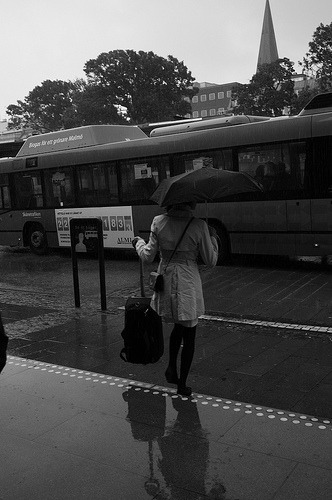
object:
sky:
[0, 1, 331, 120]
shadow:
[121, 386, 225, 498]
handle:
[139, 258, 146, 296]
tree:
[5, 47, 199, 129]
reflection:
[123, 383, 225, 499]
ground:
[1, 246, 331, 498]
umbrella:
[147, 166, 263, 208]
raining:
[1, 397, 331, 500]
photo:
[1, 1, 330, 499]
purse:
[146, 271, 165, 294]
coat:
[134, 206, 220, 322]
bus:
[0, 93, 332, 257]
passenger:
[275, 158, 285, 178]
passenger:
[255, 163, 265, 182]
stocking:
[179, 325, 196, 385]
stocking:
[166, 323, 181, 367]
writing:
[115, 234, 133, 246]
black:
[259, 443, 330, 500]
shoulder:
[187, 214, 207, 230]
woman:
[132, 201, 219, 396]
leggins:
[168, 320, 196, 384]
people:
[262, 160, 273, 191]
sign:
[69, 217, 107, 311]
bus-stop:
[1, 91, 330, 309]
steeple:
[255, 0, 279, 71]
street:
[0, 287, 332, 417]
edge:
[143, 467, 228, 499]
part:
[1, 370, 122, 499]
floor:
[1, 243, 330, 499]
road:
[0, 254, 332, 325]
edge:
[217, 262, 331, 326]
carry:
[120, 234, 165, 365]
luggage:
[118, 296, 165, 364]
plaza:
[0, 356, 330, 500]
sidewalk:
[0, 355, 332, 500]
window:
[12, 173, 43, 210]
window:
[45, 170, 73, 207]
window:
[123, 164, 170, 207]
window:
[238, 149, 310, 194]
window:
[77, 167, 91, 205]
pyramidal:
[255, 0, 278, 75]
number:
[57, 218, 63, 230]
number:
[62, 218, 70, 230]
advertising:
[70, 218, 102, 257]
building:
[178, 72, 316, 117]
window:
[198, 93, 206, 104]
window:
[207, 92, 216, 101]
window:
[216, 91, 225, 100]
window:
[199, 108, 209, 118]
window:
[191, 109, 199, 118]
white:
[254, 405, 262, 408]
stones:
[244, 403, 251, 408]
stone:
[315, 423, 329, 431]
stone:
[266, 412, 276, 420]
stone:
[289, 412, 295, 417]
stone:
[32, 409, 155, 463]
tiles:
[269, 286, 296, 301]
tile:
[201, 371, 259, 401]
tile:
[234, 358, 278, 377]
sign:
[54, 206, 133, 248]